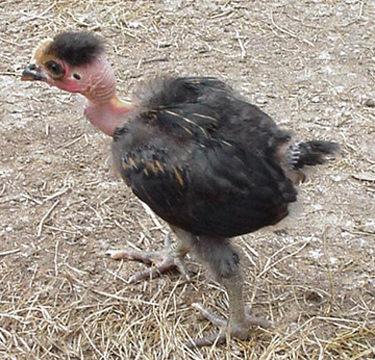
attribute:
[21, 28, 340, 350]
bird — baby, ostrich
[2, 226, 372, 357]
hay — dried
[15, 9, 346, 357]
bird — small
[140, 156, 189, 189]
feather — brown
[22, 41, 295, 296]
turkey — baby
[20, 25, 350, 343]
turkey — baby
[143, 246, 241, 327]
gray legs — grey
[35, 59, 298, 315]
turkey — baby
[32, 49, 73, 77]
eyes — black color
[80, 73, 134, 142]
neck — pinkish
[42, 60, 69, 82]
eye — large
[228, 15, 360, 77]
ground — brown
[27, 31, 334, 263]
turkey — baby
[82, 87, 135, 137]
neck — pink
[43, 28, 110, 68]
feathers — black, fuzzy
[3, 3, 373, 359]
hay — dried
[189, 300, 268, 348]
foot — brown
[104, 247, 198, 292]
foot — brown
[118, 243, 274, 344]
feet — large